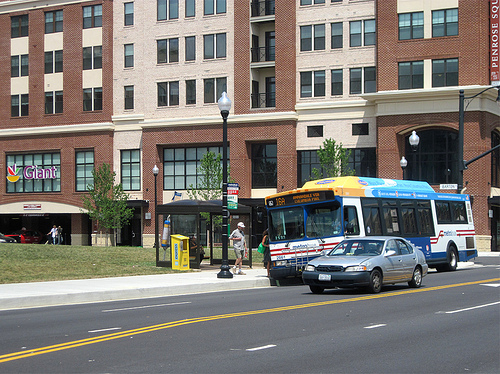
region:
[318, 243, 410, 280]
this is a car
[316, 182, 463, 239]
this is a bus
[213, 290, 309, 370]
this the road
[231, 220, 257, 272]
this is a man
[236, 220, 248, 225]
this is a cap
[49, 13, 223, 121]
this is a building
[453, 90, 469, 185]
this is a pole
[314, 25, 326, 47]
this is a window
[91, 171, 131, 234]
this is a tree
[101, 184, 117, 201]
the tree has green leaves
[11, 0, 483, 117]
lots of building windows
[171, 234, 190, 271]
yellow stand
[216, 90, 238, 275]
bus sign hanging from a black lightpost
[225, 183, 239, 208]
multicolored bus sign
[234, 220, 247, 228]
hat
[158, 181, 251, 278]
man at a bus stop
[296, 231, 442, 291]
gray vehicle on the street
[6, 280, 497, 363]
yellow and white lines on a street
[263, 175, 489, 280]
non-moving multicolored bus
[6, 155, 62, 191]
design on window reading Giant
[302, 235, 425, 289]
The car driving next to the bus.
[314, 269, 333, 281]
The license plate on the car.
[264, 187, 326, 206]
The marquee display on the front of the bus.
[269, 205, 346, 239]
The front windows of the bus.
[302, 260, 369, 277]
The headlights of the car in the street next to the bus.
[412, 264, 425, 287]
The back tire of the car next to the bus.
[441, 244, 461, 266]
The back tire of the bus.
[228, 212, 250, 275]
The man standing next to the light post waiting to get on the bus.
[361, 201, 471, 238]
The passenger windows on the side of the bus.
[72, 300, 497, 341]
The white dashed lines in the street.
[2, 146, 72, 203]
A sign on the building that says Giant.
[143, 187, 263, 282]
A bus stop.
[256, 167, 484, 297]
A bus at the bus stop.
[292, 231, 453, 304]
A car on the road.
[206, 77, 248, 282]
A street light.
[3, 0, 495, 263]
A building is in the background.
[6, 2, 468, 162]
The building has a lot of windows.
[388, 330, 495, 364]
The road is black.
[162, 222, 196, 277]
A yellow object.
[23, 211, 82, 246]
People are in the background.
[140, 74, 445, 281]
lamps on tall black posts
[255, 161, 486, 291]
a bus on the side of the road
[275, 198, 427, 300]
small car driving by bus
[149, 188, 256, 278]
a black bus stop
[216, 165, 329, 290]
man moving towards bus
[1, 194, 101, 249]
person near a building's entrance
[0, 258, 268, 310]
clean sidewalk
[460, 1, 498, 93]
red sign with white text on side of building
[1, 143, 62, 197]
name with colorful logo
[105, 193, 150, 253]
black doors of building